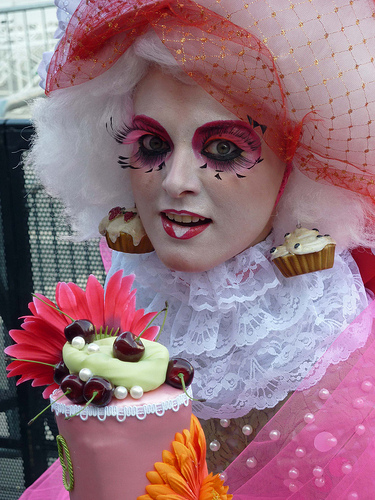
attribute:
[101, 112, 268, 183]
eyelashes — long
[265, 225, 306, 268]
frosting — white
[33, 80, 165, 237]
hair — white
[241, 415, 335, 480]
veil — pink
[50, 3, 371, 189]
hairnet — red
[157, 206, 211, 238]
lips — pink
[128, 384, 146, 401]
pearl — white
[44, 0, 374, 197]
net — red, gold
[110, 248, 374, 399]
collar — white, lace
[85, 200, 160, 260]
earring — cupcake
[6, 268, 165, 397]
flower — pink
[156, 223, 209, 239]
lips — pink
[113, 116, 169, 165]
lashes — long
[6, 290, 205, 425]
cherries — dark red, red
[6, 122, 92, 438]
fence — black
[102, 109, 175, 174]
eyelashes — long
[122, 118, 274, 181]
eyelashes — long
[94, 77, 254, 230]
beads — white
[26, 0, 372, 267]
wig — white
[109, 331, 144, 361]
cherry — red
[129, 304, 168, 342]
stem — green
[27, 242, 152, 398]
flower — orange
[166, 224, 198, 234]
lipstick — pink, white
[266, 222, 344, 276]
cupcake — fake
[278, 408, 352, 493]
chiffon — pink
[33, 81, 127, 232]
wig — white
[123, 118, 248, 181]
eyes — wild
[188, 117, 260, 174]
make-up — heavy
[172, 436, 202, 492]
petals — orange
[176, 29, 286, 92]
veil — red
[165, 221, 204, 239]
lipstick — pink, white